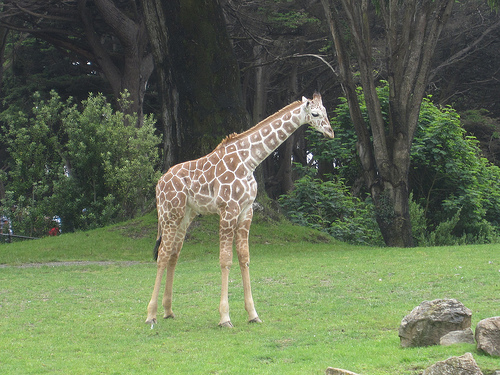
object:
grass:
[0, 206, 500, 375]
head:
[301, 88, 335, 139]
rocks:
[438, 326, 475, 345]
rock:
[397, 298, 472, 350]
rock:
[422, 351, 484, 375]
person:
[49, 221, 61, 238]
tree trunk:
[361, 177, 414, 248]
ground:
[0, 207, 500, 375]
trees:
[474, 0, 500, 113]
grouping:
[317, 0, 500, 247]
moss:
[168, 0, 233, 160]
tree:
[436, 0, 500, 108]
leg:
[233, 203, 265, 324]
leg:
[215, 186, 242, 331]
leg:
[142, 172, 186, 325]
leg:
[161, 204, 197, 321]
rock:
[474, 316, 500, 359]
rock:
[324, 365, 359, 375]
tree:
[292, 0, 310, 166]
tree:
[0, 0, 55, 79]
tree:
[223, 0, 282, 129]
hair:
[153, 236, 163, 263]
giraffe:
[143, 90, 336, 332]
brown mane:
[217, 130, 237, 147]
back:
[162, 140, 237, 175]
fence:
[0, 220, 43, 244]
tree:
[268, 0, 320, 198]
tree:
[0, 0, 169, 129]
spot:
[260, 124, 273, 137]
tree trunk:
[145, 0, 273, 195]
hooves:
[218, 320, 237, 329]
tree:
[314, 0, 447, 251]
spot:
[230, 178, 245, 202]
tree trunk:
[277, 135, 294, 196]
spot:
[170, 196, 180, 207]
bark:
[373, 177, 418, 247]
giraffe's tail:
[151, 217, 163, 263]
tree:
[157, 0, 267, 199]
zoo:
[0, 0, 500, 375]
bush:
[0, 87, 165, 244]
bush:
[276, 78, 500, 247]